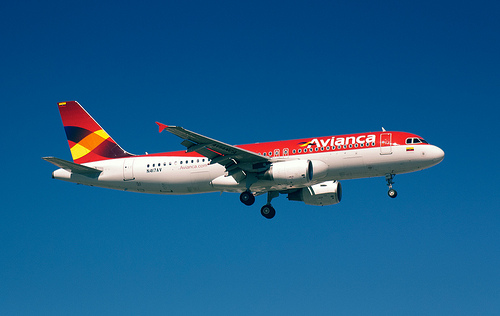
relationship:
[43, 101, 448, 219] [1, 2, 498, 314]
plane flying in sky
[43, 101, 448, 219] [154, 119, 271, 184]
plane has wing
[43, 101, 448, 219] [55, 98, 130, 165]
plane has tail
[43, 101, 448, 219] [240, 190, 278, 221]
plane has wheels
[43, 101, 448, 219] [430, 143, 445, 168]
plane has nose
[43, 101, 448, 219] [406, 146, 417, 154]
plane has flag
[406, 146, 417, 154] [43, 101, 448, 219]
flag on side of plane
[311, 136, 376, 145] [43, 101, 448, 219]
lettering on side of plane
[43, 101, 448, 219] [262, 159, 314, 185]
plane has engine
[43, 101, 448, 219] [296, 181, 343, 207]
plane has engine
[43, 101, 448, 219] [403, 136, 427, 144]
plane has cock pit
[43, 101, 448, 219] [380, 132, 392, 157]
plane has door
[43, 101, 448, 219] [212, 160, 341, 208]
plane has fusel lodge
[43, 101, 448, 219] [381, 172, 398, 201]
plane has wheels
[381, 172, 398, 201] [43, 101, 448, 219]
wheels on front end of plane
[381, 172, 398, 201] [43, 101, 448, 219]
wheels on front of plane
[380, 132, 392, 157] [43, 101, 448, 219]
door on side of plane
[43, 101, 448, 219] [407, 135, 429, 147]
plane has front windows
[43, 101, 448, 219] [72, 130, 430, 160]
plane has stripe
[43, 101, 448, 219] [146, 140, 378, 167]
plane has windows